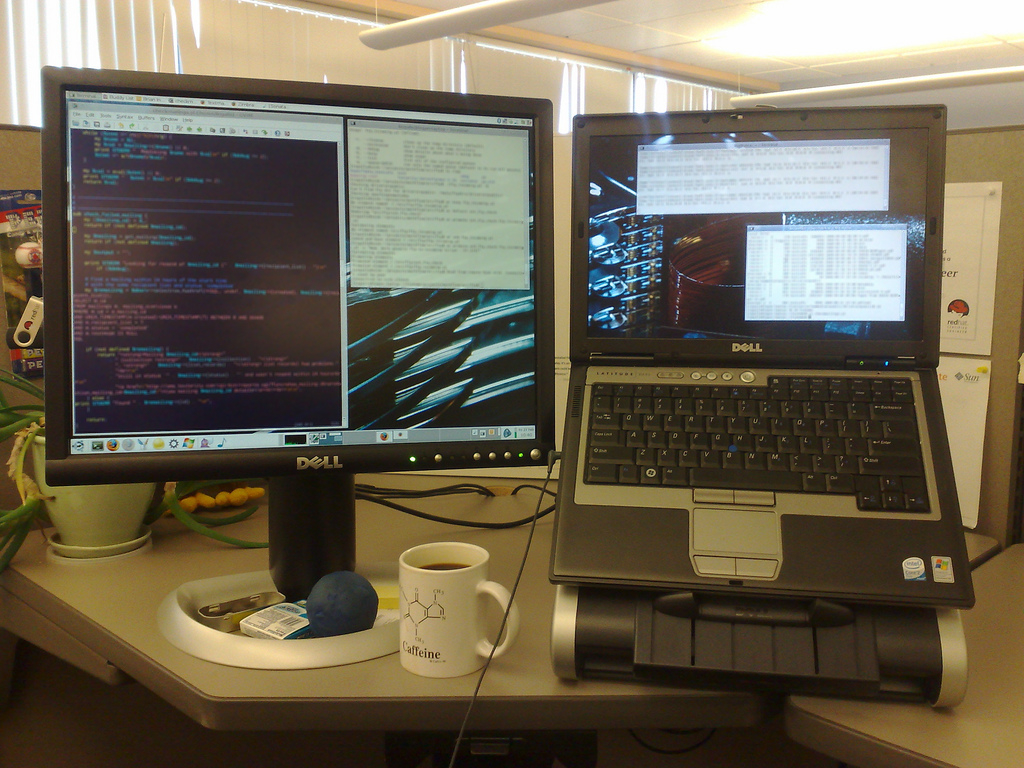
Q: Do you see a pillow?
A: No, there are no pillows.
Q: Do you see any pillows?
A: No, there are no pillows.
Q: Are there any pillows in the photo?
A: No, there are no pillows.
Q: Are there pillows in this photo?
A: No, there are no pillows.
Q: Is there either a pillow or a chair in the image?
A: No, there are no pillows or chairs.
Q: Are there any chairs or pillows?
A: No, there are no pillows or chairs.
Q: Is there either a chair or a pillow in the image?
A: No, there are no pillows or chairs.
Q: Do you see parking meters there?
A: No, there are no parking meters.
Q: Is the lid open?
A: Yes, the lid is open.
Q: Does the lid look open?
A: Yes, the lid is open.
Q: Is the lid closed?
A: No, the lid is open.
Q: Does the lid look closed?
A: No, the lid is open.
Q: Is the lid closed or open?
A: The lid is open.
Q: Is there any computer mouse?
A: No, there are no computer mice.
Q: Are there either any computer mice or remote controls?
A: No, there are no computer mice or remote controls.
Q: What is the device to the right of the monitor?
A: The device is a screen.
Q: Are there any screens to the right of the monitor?
A: Yes, there is a screen to the right of the monitor.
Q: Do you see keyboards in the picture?
A: Yes, there is a keyboard.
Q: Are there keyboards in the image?
A: Yes, there is a keyboard.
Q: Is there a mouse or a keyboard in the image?
A: Yes, there is a keyboard.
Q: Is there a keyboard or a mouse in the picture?
A: Yes, there is a keyboard.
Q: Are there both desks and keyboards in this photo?
A: Yes, there are both a keyboard and a desk.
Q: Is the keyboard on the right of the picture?
A: Yes, the keyboard is on the right of the image.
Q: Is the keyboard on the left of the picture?
A: No, the keyboard is on the right of the image.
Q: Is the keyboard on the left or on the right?
A: The keyboard is on the right of the image.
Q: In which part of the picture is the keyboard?
A: The keyboard is on the right of the image.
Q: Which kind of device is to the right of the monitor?
A: The device is a keyboard.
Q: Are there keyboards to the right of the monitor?
A: Yes, there is a keyboard to the right of the monitor.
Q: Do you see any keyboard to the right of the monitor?
A: Yes, there is a keyboard to the right of the monitor.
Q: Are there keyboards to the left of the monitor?
A: No, the keyboard is to the right of the monitor.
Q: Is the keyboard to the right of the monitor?
A: Yes, the keyboard is to the right of the monitor.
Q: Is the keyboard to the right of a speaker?
A: No, the keyboard is to the right of the monitor.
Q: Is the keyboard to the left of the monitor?
A: No, the keyboard is to the right of the monitor.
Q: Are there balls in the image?
A: Yes, there is a ball.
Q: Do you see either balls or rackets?
A: Yes, there is a ball.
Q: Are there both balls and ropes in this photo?
A: No, there is a ball but no ropes.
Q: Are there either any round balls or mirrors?
A: Yes, there is a round ball.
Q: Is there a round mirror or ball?
A: Yes, there is a round ball.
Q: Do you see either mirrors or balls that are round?
A: Yes, the ball is round.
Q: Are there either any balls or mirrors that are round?
A: Yes, the ball is round.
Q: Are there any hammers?
A: No, there are no hammers.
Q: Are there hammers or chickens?
A: No, there are no hammers or chickens.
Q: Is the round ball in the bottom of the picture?
A: Yes, the ball is in the bottom of the image.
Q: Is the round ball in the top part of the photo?
A: No, the ball is in the bottom of the image.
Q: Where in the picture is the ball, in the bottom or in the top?
A: The ball is in the bottom of the image.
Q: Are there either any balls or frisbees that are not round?
A: No, there is a ball but it is round.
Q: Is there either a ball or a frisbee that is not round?
A: No, there is a ball but it is round.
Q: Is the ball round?
A: Yes, the ball is round.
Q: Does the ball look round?
A: Yes, the ball is round.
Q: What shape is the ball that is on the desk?
A: The ball is round.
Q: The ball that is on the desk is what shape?
A: The ball is round.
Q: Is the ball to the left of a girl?
A: No, the ball is to the left of a computer.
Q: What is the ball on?
A: The ball is on the desk.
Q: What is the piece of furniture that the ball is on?
A: The piece of furniture is a desk.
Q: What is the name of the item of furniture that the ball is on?
A: The piece of furniture is a desk.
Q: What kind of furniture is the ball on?
A: The ball is on the desk.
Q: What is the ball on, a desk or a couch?
A: The ball is on a desk.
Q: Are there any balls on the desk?
A: Yes, there is a ball on the desk.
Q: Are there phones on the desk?
A: No, there is a ball on the desk.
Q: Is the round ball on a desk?
A: Yes, the ball is on a desk.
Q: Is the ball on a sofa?
A: No, the ball is on a desk.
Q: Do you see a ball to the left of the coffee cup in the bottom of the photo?
A: Yes, there is a ball to the left of the coffee cup.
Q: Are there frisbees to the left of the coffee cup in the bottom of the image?
A: No, there is a ball to the left of the coffee cup.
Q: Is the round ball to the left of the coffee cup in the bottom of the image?
A: Yes, the ball is to the left of the coffee cup.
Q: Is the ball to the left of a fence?
A: No, the ball is to the left of the coffee cup.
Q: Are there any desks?
A: Yes, there is a desk.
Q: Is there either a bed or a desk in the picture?
A: Yes, there is a desk.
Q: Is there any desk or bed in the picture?
A: Yes, there is a desk.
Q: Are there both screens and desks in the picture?
A: Yes, there are both a desk and a screen.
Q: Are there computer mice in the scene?
A: No, there are no computer mice.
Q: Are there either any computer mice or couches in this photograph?
A: No, there are no computer mice or couches.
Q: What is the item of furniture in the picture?
A: The piece of furniture is a desk.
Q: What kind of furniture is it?
A: The piece of furniture is a desk.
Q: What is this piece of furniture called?
A: This is a desk.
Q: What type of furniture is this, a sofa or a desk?
A: This is a desk.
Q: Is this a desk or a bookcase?
A: This is a desk.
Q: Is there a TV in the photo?
A: No, there are no televisions.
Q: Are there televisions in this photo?
A: No, there are no televisions.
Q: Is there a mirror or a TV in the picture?
A: No, there are no televisions or mirrors.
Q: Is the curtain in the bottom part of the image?
A: No, the curtain is in the top of the image.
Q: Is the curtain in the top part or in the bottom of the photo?
A: The curtain is in the top of the image.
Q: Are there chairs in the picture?
A: No, there are no chairs.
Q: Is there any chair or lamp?
A: No, there are no chairs or lamps.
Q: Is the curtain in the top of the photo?
A: Yes, the curtain is in the top of the image.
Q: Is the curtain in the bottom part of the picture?
A: No, the curtain is in the top of the image.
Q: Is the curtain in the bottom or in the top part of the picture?
A: The curtain is in the top of the image.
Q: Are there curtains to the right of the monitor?
A: Yes, there is a curtain to the right of the monitor.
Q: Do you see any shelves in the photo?
A: No, there are no shelves.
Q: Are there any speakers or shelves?
A: No, there are no shelves or speakers.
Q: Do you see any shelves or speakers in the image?
A: No, there are no shelves or speakers.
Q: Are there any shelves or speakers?
A: No, there are no shelves or speakers.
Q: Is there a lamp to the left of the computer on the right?
A: No, there is a screen to the left of the computer.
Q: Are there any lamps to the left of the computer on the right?
A: No, there is a screen to the left of the computer.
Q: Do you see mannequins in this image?
A: No, there are no mannequins.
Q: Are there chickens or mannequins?
A: No, there are no mannequins or chickens.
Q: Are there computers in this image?
A: Yes, there is a computer.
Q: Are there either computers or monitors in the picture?
A: Yes, there is a computer.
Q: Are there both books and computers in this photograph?
A: No, there is a computer but no books.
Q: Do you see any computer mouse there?
A: No, there are no computer mice.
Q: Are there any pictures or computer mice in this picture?
A: No, there are no computer mice or pictures.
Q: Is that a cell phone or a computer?
A: That is a computer.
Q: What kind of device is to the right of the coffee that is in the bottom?
A: The device is a computer.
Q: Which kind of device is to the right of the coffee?
A: The device is a computer.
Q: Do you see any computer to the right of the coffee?
A: Yes, there is a computer to the right of the coffee.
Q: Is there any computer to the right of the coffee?
A: Yes, there is a computer to the right of the coffee.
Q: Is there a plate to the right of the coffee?
A: No, there is a computer to the right of the coffee.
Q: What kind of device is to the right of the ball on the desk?
A: The device is a computer.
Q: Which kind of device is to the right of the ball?
A: The device is a computer.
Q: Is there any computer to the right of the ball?
A: Yes, there is a computer to the right of the ball.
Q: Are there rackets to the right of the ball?
A: No, there is a computer to the right of the ball.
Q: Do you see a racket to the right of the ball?
A: No, there is a computer to the right of the ball.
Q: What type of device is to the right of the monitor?
A: The device is a computer.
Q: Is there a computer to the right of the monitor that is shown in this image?
A: Yes, there is a computer to the right of the monitor.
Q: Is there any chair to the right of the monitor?
A: No, there is a computer to the right of the monitor.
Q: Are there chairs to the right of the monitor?
A: No, there is a computer to the right of the monitor.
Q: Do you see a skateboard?
A: No, there are no skateboards.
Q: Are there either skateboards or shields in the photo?
A: No, there are no skateboards or shields.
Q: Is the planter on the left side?
A: Yes, the planter is on the left of the image.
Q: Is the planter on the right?
A: No, the planter is on the left of the image.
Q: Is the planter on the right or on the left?
A: The planter is on the left of the image.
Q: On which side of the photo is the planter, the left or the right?
A: The planter is on the left of the image.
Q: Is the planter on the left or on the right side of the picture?
A: The planter is on the left of the image.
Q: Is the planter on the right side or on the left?
A: The planter is on the left of the image.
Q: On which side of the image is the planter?
A: The planter is on the left of the image.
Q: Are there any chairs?
A: No, there are no chairs.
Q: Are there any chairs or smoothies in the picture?
A: No, there are no chairs or smoothies.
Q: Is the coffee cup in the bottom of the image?
A: Yes, the coffee cup is in the bottom of the image.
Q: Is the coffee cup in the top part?
A: No, the coffee cup is in the bottom of the image.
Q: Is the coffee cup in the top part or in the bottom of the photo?
A: The coffee cup is in the bottom of the image.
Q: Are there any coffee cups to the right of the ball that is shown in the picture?
A: Yes, there is a coffee cup to the right of the ball.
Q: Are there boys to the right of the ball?
A: No, there is a coffee cup to the right of the ball.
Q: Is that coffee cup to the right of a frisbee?
A: No, the coffee cup is to the right of the ball.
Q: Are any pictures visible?
A: No, there are no pictures.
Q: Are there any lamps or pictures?
A: No, there are no pictures or lamps.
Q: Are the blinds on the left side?
A: Yes, the blinds are on the left of the image.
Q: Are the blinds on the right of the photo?
A: No, the blinds are on the left of the image.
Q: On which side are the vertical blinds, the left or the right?
A: The blinds are on the left of the image.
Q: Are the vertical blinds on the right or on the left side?
A: The blinds are on the left of the image.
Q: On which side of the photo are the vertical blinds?
A: The blinds are on the left of the image.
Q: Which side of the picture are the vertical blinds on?
A: The blinds are on the left of the image.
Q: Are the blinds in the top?
A: Yes, the blinds are in the top of the image.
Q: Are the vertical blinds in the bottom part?
A: No, the blinds are in the top of the image.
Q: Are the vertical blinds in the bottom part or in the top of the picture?
A: The blinds are in the top of the image.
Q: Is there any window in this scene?
A: Yes, there are windows.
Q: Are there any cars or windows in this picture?
A: Yes, there are windows.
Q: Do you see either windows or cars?
A: Yes, there are windows.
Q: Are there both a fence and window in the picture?
A: No, there are windows but no fences.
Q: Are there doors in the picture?
A: No, there are no doors.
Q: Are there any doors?
A: No, there are no doors.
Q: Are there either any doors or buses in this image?
A: No, there are no doors or buses.